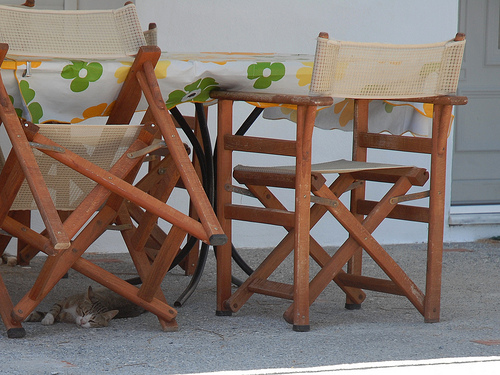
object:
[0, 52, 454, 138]
tablecloth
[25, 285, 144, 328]
cat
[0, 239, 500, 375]
ground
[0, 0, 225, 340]
chair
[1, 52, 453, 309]
table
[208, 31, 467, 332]
chair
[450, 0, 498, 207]
door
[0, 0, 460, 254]
wall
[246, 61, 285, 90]
flower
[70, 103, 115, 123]
flower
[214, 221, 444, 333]
legs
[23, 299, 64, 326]
legs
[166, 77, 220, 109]
flower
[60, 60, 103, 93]
flower